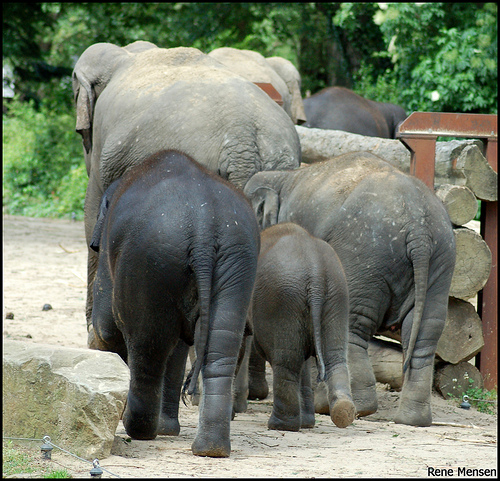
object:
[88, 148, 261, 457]
elephant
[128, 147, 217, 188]
hair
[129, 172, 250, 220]
back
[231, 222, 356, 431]
elephant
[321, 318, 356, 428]
leg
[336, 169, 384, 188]
paint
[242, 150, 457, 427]
elephants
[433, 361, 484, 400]
logs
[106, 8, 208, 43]
leaves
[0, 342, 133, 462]
rock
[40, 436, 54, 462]
hooks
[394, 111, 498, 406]
rack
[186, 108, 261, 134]
skin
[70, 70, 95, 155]
ear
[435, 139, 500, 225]
log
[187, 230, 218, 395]
tails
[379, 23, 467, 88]
foilage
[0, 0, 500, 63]
background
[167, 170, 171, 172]
spots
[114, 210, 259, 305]
rump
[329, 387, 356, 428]
foot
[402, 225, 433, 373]
tail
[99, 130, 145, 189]
wrinkles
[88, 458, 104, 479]
anchor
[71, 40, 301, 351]
elephant